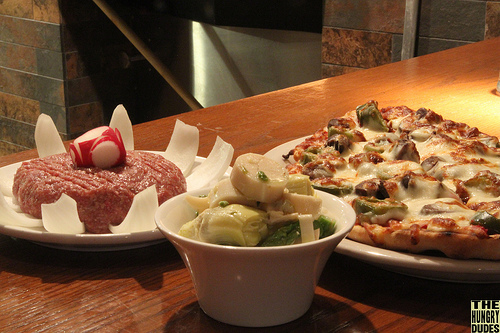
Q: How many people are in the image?
A: 0.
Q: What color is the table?
A: Brown.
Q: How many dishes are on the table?
A: 3.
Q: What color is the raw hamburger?
A: Red.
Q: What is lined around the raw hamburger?
A: Onions.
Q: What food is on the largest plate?
A: Pizza.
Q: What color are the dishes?
A: White.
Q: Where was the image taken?
A: At a restaurant.